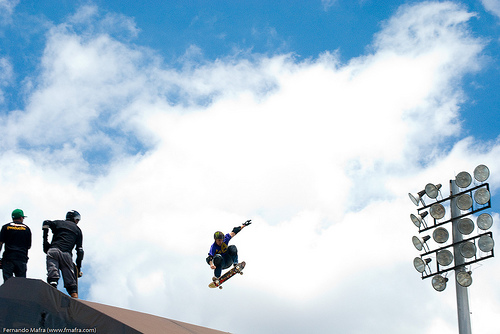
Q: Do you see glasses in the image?
A: No, there are no glasses.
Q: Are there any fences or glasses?
A: No, there are no glasses or fences.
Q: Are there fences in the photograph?
A: No, there are no fences.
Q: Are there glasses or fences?
A: No, there are no fences or glasses.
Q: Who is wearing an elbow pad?
A: The man is wearing an elbow pad.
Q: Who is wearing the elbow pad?
A: The man is wearing an elbow pad.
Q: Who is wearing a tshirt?
A: The man is wearing a tshirt.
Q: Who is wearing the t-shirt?
A: The man is wearing a tshirt.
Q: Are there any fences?
A: No, there are no fences.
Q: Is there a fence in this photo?
A: No, there are no fences.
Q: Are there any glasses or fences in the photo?
A: No, there are no fences or glasses.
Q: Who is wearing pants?
A: The man is wearing pants.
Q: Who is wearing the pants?
A: The man is wearing pants.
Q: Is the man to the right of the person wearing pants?
A: Yes, the man is wearing pants.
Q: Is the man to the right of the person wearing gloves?
A: No, the man is wearing pants.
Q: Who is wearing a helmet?
A: The man is wearing a helmet.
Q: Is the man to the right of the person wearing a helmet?
A: Yes, the man is wearing a helmet.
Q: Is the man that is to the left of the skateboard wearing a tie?
A: No, the man is wearing a helmet.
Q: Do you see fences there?
A: No, there are no fences.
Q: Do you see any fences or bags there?
A: No, there are no fences or bags.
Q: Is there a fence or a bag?
A: No, there are no fences or bags.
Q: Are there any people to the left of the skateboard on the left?
A: Yes, there is a person to the left of the skateboard.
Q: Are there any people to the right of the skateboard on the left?
A: No, the person is to the left of the skateboard.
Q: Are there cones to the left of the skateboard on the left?
A: No, there is a person to the left of the skateboard.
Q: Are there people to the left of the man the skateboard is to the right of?
A: Yes, there is a person to the left of the man.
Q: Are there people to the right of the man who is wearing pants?
A: No, the person is to the left of the man.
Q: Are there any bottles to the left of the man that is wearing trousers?
A: No, there is a person to the left of the man.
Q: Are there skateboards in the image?
A: Yes, there is a skateboard.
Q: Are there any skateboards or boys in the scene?
A: Yes, there is a skateboard.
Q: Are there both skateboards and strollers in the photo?
A: No, there is a skateboard but no strollers.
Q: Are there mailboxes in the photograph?
A: No, there are no mailboxes.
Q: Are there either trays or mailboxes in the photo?
A: No, there are no mailboxes or trays.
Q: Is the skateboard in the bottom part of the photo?
A: Yes, the skateboard is in the bottom of the image.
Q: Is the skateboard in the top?
A: No, the skateboard is in the bottom of the image.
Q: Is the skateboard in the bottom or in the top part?
A: The skateboard is in the bottom of the image.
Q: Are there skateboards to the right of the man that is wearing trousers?
A: Yes, there is a skateboard to the right of the man.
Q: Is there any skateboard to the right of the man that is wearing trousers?
A: Yes, there is a skateboard to the right of the man.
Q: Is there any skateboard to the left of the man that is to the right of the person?
A: No, the skateboard is to the right of the man.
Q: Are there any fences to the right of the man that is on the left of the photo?
A: No, there is a skateboard to the right of the man.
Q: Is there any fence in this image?
A: No, there are no fences.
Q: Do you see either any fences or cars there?
A: No, there are no fences or cars.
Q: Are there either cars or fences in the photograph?
A: No, there are no fences or cars.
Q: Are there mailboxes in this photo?
A: No, there are no mailboxes.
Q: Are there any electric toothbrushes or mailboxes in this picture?
A: No, there are no mailboxes or electric toothbrushes.